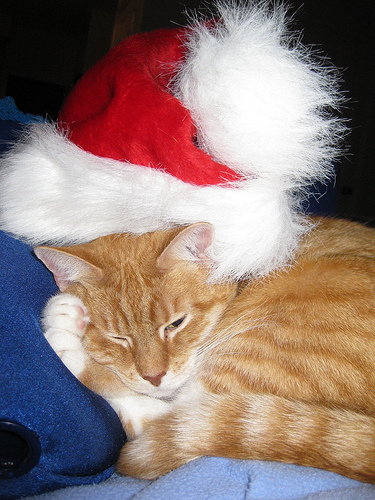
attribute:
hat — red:
[3, 10, 359, 274]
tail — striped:
[100, 393, 365, 479]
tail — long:
[116, 407, 374, 482]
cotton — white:
[161, 2, 356, 189]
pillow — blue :
[3, 354, 61, 403]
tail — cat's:
[125, 385, 372, 480]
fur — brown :
[307, 275, 352, 310]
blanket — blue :
[182, 468, 282, 498]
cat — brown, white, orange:
[27, 210, 373, 496]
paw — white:
[43, 292, 101, 352]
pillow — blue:
[7, 105, 123, 490]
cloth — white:
[1, 15, 344, 272]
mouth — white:
[113, 354, 198, 404]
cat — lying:
[39, 228, 372, 465]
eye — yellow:
[154, 311, 192, 335]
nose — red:
[136, 357, 170, 386]